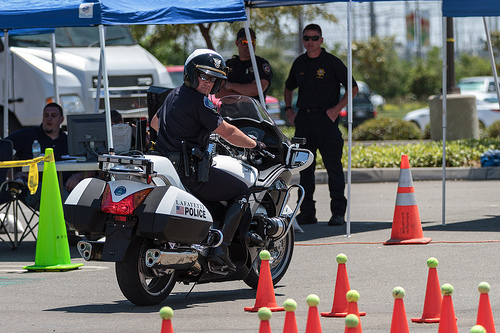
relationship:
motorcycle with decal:
[101, 148, 290, 272] [171, 195, 215, 233]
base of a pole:
[429, 94, 474, 141] [444, 9, 456, 89]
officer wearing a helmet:
[137, 48, 275, 278] [177, 42, 254, 98]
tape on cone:
[392, 167, 417, 187] [381, 151, 431, 244]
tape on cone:
[392, 190, 422, 208] [381, 151, 431, 244]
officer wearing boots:
[137, 48, 275, 278] [208, 179, 239, 265]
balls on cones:
[254, 292, 320, 318] [145, 251, 500, 331]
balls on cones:
[257, 244, 452, 269] [145, 251, 500, 331]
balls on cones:
[345, 279, 490, 304] [145, 251, 500, 331]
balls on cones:
[156, 303, 177, 320] [145, 251, 500, 331]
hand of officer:
[327, 109, 336, 124] [280, 18, 354, 233]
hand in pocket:
[327, 109, 336, 124] [323, 110, 339, 132]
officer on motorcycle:
[137, 48, 275, 278] [69, 92, 302, 302]